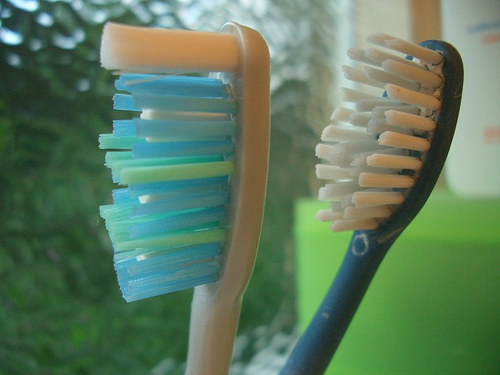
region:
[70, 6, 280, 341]
white blue and green toothbrush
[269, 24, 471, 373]
blue and white toothbrush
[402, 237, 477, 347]
green grass on the ground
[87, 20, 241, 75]
bigger white bristle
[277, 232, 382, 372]
blue plastic handle of a toothbrush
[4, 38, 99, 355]
green bushes outside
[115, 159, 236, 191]
small light green bristle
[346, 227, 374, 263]
peeling blue pastic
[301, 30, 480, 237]
several white bristles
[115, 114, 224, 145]
baby blue toothbrush bristles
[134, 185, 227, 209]
the blue bristle of a toothbrush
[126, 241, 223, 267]
the blue bristle of a toothbrush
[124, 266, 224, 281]
the blue bristle of a toothbrush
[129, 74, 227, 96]
the blue bristle of a toothbrush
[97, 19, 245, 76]
the white bristle of a toothbrush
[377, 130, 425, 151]
the white bristle of a toothbrush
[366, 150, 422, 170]
the white bristle of a toothbrush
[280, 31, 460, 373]
a blue toothbrush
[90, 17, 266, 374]
a white toothbrush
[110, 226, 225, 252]
a green bristle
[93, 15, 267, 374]
white tooth brush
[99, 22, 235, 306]
white and green toothbrush bristles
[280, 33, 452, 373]
dark blue toothbrush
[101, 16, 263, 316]
bristles on new toothbrush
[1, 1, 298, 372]
green leaves on tree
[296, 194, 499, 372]
lime green plastic container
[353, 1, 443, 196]
ivory and brown stone wall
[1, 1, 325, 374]
glass covered bathroom window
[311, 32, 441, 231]
white bristles on toothbrush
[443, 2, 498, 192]
white board with writing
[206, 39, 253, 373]
White toothbrush next to dark toothbrush.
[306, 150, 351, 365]
Dark toothbrush next to white tooth brush.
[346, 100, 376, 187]
White bristles on toothbrush.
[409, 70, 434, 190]
Scum in the head of toothbrush.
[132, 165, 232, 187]
Light green bristle on brush.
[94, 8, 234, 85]
Large white bristle on brush.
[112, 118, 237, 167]
Blue bristles on brush.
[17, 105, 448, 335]
2 toothbrushes near each other.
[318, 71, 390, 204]
Bristles are different lengths on brush.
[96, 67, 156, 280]
Bristles are different sizes and lengths on brush.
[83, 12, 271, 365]
white toothbrush head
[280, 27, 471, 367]
blue toothbrush head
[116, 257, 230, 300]
blue bristles on a toothbrush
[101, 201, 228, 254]
green bristle on a toothbrush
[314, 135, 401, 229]
white bristles on a toothbrush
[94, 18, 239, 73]
longest bristles on a toothbrush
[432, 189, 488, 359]
green bathroom cup for rinsing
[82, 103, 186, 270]
blue and green bristles on a toothbrush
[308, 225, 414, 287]
blue toothbrush handle with white spots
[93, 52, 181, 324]
bristles of varying lengths